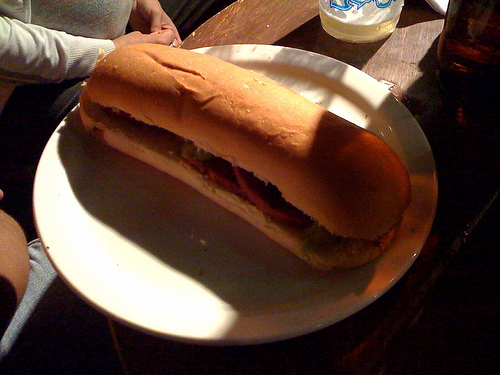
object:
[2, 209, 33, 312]
brown object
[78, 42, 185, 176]
back portion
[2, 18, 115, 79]
sleeve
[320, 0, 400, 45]
cake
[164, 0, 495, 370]
table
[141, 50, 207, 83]
crease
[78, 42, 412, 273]
bread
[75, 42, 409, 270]
bun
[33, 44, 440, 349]
plate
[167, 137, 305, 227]
tomatoes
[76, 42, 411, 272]
sandwich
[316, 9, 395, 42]
bottom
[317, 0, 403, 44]
cup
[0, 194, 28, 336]
elbow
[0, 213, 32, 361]
man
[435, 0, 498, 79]
bottom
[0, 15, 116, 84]
arm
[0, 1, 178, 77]
man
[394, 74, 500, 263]
shadow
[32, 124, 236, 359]
light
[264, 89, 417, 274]
front portion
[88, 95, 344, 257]
hot dog